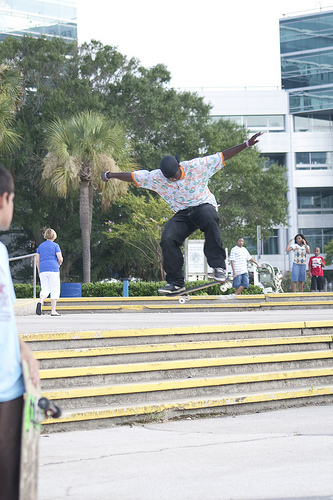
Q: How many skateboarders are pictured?
A: One.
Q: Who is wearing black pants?
A: The skateboarder.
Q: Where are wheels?
A: On the skateboard.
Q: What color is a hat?
A: Black.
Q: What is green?
A: Trees.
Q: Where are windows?
A: On buildings.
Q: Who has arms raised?
A: Skateboarder.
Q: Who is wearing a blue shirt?
A: Woman on left.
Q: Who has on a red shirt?
A: Boy on right.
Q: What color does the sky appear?
A: White.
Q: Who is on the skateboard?
A: The man in black pants.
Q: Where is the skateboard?
A: On the steps.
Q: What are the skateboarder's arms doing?
A: Being outstretched.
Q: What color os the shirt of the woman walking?
A: Blue.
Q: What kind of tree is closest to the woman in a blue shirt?
A: Palm.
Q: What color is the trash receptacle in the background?
A: Blue.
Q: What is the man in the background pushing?
A: A baby stroller.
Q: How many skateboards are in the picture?
A: Two.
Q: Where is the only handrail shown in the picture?
A: On the left.